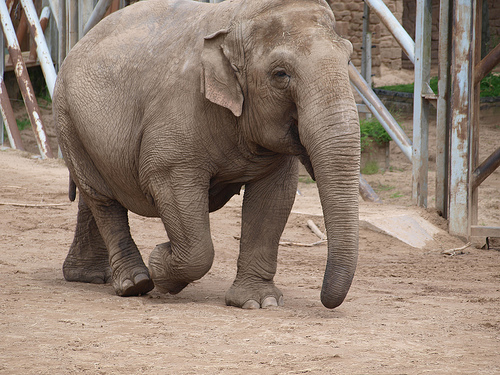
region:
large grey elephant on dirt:
[10, 6, 390, 344]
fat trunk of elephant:
[300, 69, 375, 310]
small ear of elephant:
[175, 22, 247, 129]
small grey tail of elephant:
[62, 178, 80, 206]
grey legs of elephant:
[67, 176, 294, 313]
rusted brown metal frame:
[465, 18, 479, 248]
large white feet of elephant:
[230, 286, 295, 321]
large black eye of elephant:
[267, 61, 298, 86]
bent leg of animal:
[138, 208, 230, 302]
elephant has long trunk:
[269, 60, 387, 310]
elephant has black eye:
[258, 58, 302, 97]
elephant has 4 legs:
[71, 157, 280, 316]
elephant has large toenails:
[109, 258, 161, 315]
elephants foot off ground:
[128, 219, 242, 312]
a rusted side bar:
[426, 25, 482, 242]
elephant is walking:
[68, 41, 390, 304]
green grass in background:
[361, 75, 488, 160]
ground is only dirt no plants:
[113, 312, 373, 367]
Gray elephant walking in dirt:
[41, 0, 363, 307]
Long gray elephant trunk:
[310, 63, 362, 303]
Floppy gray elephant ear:
[201, 28, 241, 118]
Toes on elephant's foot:
[245, 290, 285, 308]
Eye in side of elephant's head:
[270, 63, 291, 86]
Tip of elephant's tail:
[67, 174, 80, 202]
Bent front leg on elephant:
[147, 173, 212, 295]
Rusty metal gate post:
[447, 0, 485, 232]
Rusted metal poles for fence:
[2, 3, 64, 160]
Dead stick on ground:
[2, 200, 78, 207]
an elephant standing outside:
[83, 62, 410, 358]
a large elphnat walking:
[42, 41, 449, 362]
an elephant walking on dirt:
[30, 47, 357, 361]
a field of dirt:
[49, 193, 436, 374]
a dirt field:
[100, 141, 419, 366]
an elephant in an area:
[35, 15, 446, 322]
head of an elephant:
[199, 16, 363, 156]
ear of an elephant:
[176, 10, 254, 115]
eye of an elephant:
[260, 62, 306, 91]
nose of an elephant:
[294, 157, 397, 302]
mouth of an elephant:
[290, 127, 325, 171]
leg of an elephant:
[225, 187, 288, 304]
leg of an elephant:
[143, 190, 230, 302]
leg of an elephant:
[102, 225, 162, 298]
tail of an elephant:
[50, 132, 82, 212]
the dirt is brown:
[362, 240, 476, 358]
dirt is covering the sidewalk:
[415, 220, 456, 264]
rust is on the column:
[450, 54, 477, 241]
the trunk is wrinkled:
[305, 73, 366, 308]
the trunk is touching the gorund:
[304, 56, 374, 319]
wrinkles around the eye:
[255, 43, 300, 116]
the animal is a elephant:
[57, 53, 367, 306]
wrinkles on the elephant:
[73, 70, 171, 187]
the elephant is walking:
[60, 37, 375, 314]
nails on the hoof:
[250, 291, 287, 306]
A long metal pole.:
[448, 2, 473, 242]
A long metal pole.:
[438, 8, 444, 218]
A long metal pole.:
[418, 0, 426, 211]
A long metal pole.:
[473, 40, 495, 85]